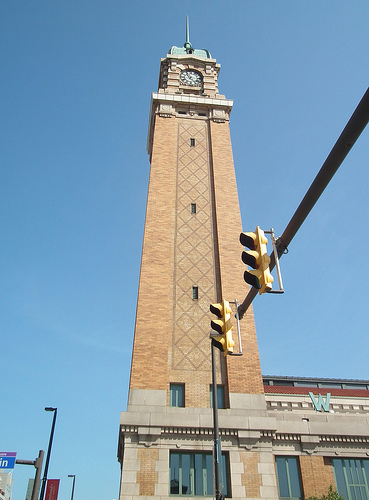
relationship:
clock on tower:
[170, 62, 217, 100] [133, 33, 264, 385]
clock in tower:
[170, 62, 217, 100] [133, 33, 264, 385]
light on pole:
[230, 219, 293, 312] [302, 127, 353, 193]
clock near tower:
[170, 62, 217, 100] [133, 33, 264, 385]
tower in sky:
[133, 33, 264, 385] [14, 60, 137, 256]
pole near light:
[302, 127, 353, 193] [230, 219, 293, 312]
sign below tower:
[5, 446, 24, 480] [133, 33, 264, 385]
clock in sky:
[170, 62, 217, 100] [14, 60, 137, 256]